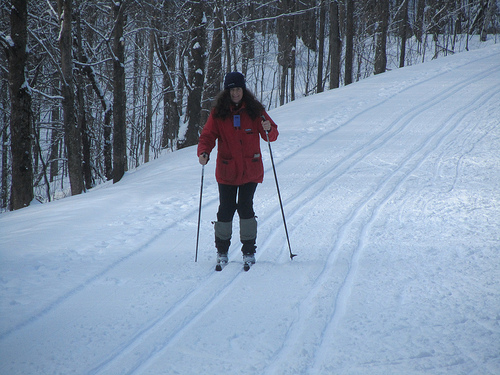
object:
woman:
[197, 68, 278, 273]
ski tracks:
[297, 85, 499, 374]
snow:
[6, 42, 496, 375]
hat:
[224, 70, 249, 89]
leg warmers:
[214, 220, 236, 252]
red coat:
[198, 91, 279, 185]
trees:
[1, 2, 499, 212]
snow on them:
[0, 2, 498, 213]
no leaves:
[0, 0, 500, 216]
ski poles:
[192, 163, 213, 262]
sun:
[2, 118, 498, 256]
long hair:
[212, 87, 267, 120]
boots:
[212, 238, 231, 272]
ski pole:
[263, 129, 298, 261]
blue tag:
[230, 111, 243, 129]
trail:
[3, 48, 498, 371]